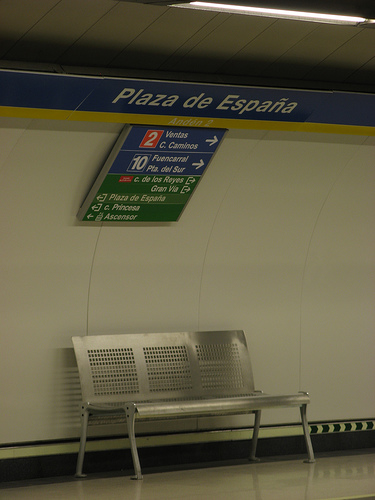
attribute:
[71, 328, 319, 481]
bench — wire mesh, metal, cold, shiny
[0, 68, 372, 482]
wall — white, curved, curving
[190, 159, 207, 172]
arrow — white, second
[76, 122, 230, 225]
sign — directional, blue, green, rectangular, informational, white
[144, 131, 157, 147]
two — white, red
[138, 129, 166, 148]
square — red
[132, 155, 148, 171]
ten — white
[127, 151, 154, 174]
square — blue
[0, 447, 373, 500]
floor — pale, shiny, waxed, reflective, tiled, white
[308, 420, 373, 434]
arrows — chevron pattern, green, black, white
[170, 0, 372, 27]
light fixture — fluoresent, long, fluorescent, tubular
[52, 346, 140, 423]
shadow — bench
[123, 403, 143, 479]
leg — on left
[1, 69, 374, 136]
sign — blue, long, yellow, plaza de espana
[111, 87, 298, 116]
writing — spanish, white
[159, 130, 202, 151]
writing — spanish, white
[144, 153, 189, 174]
writing — spanish, white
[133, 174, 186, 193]
writing — spanish, white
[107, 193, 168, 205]
writing — spanish, white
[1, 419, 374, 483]
molding — black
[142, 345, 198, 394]
section — middle, hole-filled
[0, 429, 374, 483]
stripe — black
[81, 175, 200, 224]
portion — green, white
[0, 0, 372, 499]
station — underground, tunnel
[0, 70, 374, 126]
stripe — blue